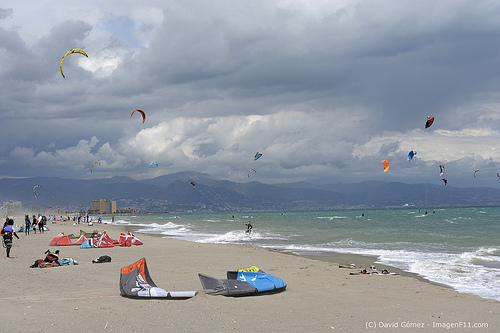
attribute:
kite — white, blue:
[437, 162, 447, 173]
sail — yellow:
[59, 45, 89, 78]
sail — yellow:
[90, 157, 100, 171]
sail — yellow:
[128, 108, 146, 125]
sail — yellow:
[472, 167, 486, 182]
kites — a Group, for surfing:
[403, 100, 439, 144]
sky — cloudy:
[11, 17, 481, 197]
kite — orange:
[372, 155, 398, 177]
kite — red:
[129, 108, 146, 125]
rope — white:
[161, 142, 221, 198]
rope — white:
[179, 163, 221, 200]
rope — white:
[196, 194, 226, 213]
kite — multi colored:
[419, 110, 445, 137]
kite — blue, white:
[407, 149, 417, 160]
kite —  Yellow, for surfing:
[411, 107, 448, 142]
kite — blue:
[373, 139, 440, 169]